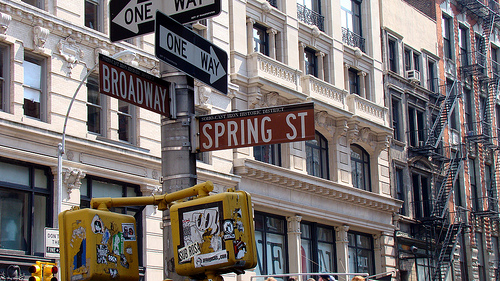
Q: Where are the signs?
A: Front of building.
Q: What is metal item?
A: Fire escape.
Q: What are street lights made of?
A: Metal.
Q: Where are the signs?
A: At intersection.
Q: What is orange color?
A: Street signs.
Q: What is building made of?
A: Stone.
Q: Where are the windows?
A: On building.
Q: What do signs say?
A: One way.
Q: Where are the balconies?
A: On building.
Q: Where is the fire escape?
A: On building.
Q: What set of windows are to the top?
A: Three windows.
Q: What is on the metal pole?
A: Signs.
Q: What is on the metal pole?
A: Street signs.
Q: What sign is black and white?
A: One way sign.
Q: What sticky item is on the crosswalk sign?
A: Stickers.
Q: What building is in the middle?
A: Brown building.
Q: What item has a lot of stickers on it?
A: Crosswalk signal.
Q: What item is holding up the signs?
A: A metal pole.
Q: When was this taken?
A: Daytime.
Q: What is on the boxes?
A: Graffiti.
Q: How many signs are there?
A: 4.